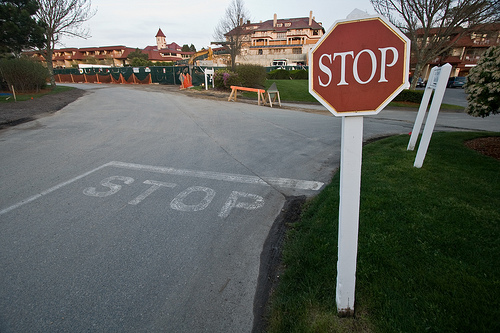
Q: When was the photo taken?
A: Daytime.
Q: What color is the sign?
A: Red.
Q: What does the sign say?
A: Stop.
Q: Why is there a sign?
A: To direct drivers.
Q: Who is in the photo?
A: Nobody.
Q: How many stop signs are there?
A: One.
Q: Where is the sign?
A: On a post.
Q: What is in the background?
A: A building.